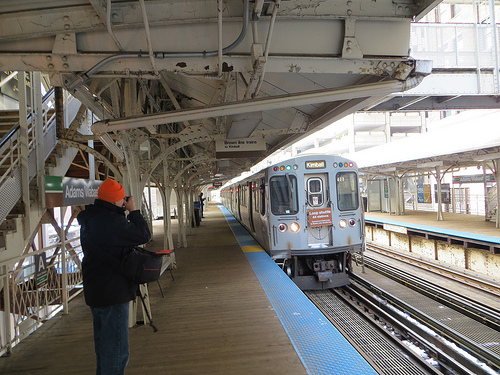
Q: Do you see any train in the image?
A: Yes, there is a train.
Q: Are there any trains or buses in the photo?
A: Yes, there is a train.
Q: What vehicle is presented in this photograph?
A: The vehicle is a train.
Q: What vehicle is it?
A: The vehicle is a train.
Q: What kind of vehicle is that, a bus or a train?
A: That is a train.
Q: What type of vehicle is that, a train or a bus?
A: That is a train.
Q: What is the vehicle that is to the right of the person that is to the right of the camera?
A: The vehicle is a train.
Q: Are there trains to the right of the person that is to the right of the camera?
A: Yes, there is a train to the right of the person.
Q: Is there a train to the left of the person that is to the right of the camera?
A: No, the train is to the right of the person.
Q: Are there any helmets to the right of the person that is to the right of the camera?
A: No, there is a train to the right of the person.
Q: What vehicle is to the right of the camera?
A: The vehicle is a train.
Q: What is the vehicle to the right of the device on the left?
A: The vehicle is a train.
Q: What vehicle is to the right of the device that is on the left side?
A: The vehicle is a train.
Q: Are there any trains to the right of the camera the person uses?
A: Yes, there is a train to the right of the camera.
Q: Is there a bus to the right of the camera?
A: No, there is a train to the right of the camera.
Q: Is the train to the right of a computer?
A: No, the train is to the right of the camera.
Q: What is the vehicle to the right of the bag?
A: The vehicle is a train.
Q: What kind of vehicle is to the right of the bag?
A: The vehicle is a train.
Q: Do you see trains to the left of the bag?
A: No, the train is to the right of the bag.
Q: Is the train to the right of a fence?
A: No, the train is to the right of a bag.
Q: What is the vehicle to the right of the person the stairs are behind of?
A: The vehicle is a train.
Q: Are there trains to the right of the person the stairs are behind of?
A: Yes, there is a train to the right of the person.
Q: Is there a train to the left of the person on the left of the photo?
A: No, the train is to the right of the person.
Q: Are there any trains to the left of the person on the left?
A: No, the train is to the right of the person.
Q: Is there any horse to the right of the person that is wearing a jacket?
A: No, there is a train to the right of the person.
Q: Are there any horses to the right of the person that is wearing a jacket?
A: No, there is a train to the right of the person.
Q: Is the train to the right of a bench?
A: No, the train is to the right of a person.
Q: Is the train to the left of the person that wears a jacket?
A: No, the train is to the right of the person.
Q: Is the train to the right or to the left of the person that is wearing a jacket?
A: The train is to the right of the person.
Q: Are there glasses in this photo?
A: No, there are no glasses.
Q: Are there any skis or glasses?
A: No, there are no glasses or skis.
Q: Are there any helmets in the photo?
A: No, there are no helmets.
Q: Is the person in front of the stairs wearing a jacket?
A: Yes, the person is wearing a jacket.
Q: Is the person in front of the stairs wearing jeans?
A: Yes, the person is wearing jeans.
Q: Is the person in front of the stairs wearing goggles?
A: No, the person is wearing jeans.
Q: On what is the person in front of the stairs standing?
A: The person is standing on the platform.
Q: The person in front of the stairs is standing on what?
A: The person is standing on the platform.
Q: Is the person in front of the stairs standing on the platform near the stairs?
A: Yes, the person is standing on the platform.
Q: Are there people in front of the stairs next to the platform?
A: Yes, there is a person in front of the stairs.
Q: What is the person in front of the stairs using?
A: The person is using a camera.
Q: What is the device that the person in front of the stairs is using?
A: The device is a camera.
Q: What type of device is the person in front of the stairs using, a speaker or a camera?
A: The person is using a camera.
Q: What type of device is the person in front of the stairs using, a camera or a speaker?
A: The person is using a camera.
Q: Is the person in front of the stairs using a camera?
A: Yes, the person is using a camera.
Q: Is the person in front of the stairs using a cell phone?
A: No, the person is using a camera.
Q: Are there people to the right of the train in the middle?
A: No, the person is to the left of the train.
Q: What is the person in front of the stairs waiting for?
A: The person is waiting for the train.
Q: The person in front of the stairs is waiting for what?
A: The person is waiting for the train.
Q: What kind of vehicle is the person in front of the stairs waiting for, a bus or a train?
A: The person is waiting for a train.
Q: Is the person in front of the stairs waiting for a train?
A: Yes, the person is waiting for a train.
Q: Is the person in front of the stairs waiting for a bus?
A: No, the person is waiting for a train.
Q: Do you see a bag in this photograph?
A: Yes, there is a bag.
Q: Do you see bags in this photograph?
A: Yes, there is a bag.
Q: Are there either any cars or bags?
A: Yes, there is a bag.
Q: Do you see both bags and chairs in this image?
A: No, there is a bag but no chairs.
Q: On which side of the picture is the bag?
A: The bag is on the left of the image.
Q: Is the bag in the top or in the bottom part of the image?
A: The bag is in the bottom of the image.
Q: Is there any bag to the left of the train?
A: Yes, there is a bag to the left of the train.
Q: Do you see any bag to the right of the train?
A: No, the bag is to the left of the train.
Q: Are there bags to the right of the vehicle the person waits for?
A: No, the bag is to the left of the train.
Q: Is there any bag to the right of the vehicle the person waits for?
A: No, the bag is to the left of the train.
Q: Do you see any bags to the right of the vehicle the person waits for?
A: No, the bag is to the left of the train.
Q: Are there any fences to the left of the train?
A: No, there is a bag to the left of the train.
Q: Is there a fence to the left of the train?
A: No, there is a bag to the left of the train.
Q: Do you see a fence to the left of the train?
A: No, there is a bag to the left of the train.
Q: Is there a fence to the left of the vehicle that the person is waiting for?
A: No, there is a bag to the left of the train.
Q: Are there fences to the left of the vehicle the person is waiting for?
A: No, there is a bag to the left of the train.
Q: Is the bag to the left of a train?
A: Yes, the bag is to the left of a train.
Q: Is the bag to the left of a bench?
A: No, the bag is to the left of a train.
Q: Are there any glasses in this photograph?
A: No, there are no glasses.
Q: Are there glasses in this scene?
A: No, there are no glasses.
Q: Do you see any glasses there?
A: No, there are no glasses.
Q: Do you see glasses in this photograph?
A: No, there are no glasses.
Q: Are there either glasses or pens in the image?
A: No, there are no glasses or pens.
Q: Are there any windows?
A: Yes, there is a window.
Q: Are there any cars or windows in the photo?
A: Yes, there is a window.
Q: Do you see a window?
A: Yes, there is a window.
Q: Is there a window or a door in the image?
A: Yes, there is a window.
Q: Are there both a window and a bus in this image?
A: No, there is a window but no buses.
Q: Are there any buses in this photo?
A: No, there are no buses.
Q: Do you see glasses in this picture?
A: No, there are no glasses.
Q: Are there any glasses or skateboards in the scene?
A: No, there are no glasses or skateboards.